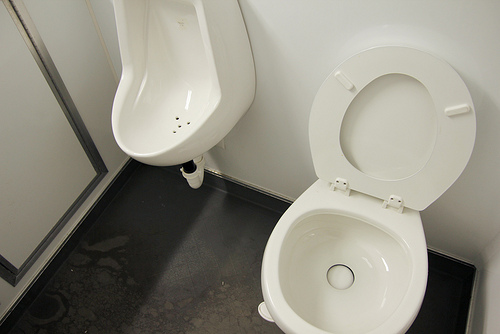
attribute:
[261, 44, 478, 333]
toilet — white, clean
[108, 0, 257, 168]
urinal — white, clean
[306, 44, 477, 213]
toilet seat — up, white, open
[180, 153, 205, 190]
pipe — white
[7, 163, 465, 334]
floor — gray, black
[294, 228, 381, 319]
water — clean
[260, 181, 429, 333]
toilet basin — white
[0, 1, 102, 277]
door — small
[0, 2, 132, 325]
wall — white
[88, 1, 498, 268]
wall — white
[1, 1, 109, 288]
frame — metal, gray